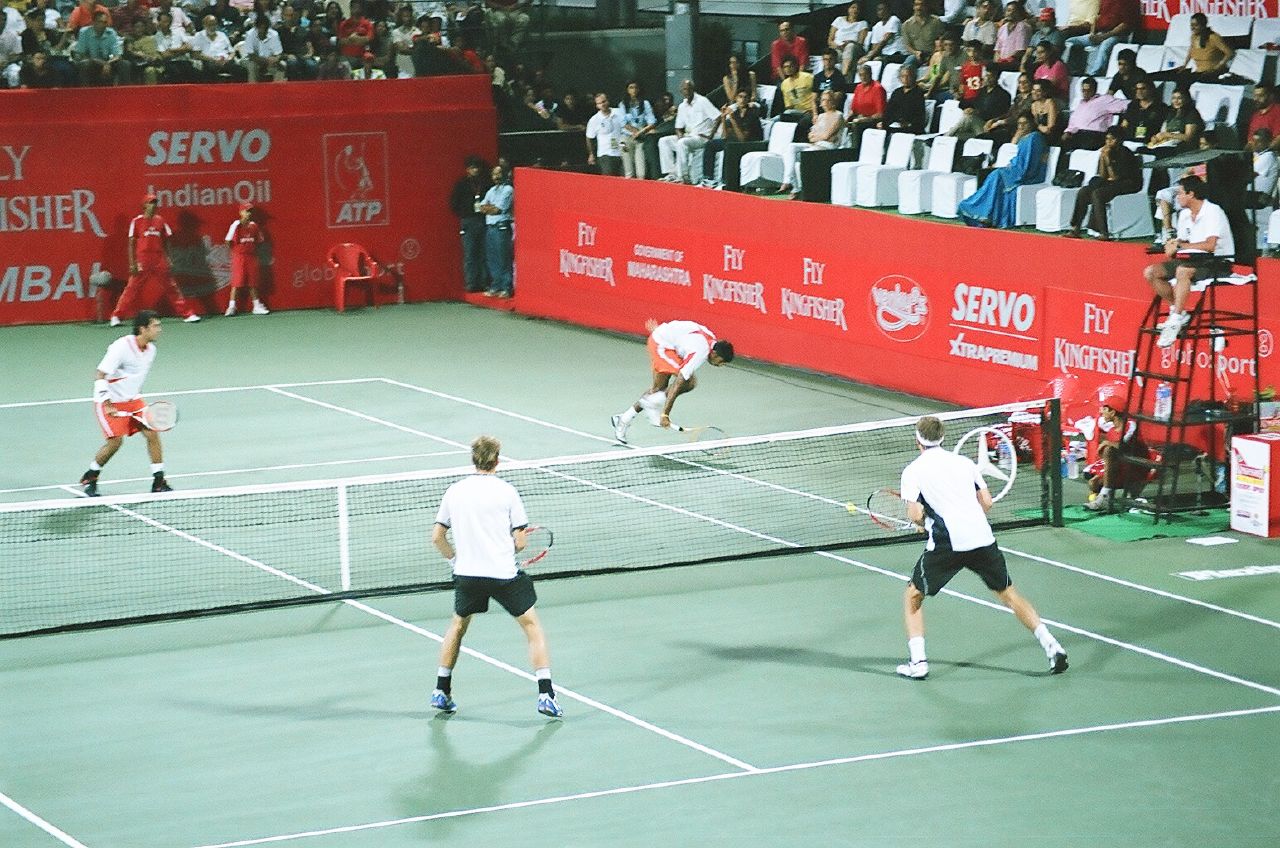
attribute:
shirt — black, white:
[892, 455, 1010, 557]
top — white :
[431, 493, 559, 574]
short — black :
[438, 558, 575, 625]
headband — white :
[894, 381, 1010, 457]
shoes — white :
[871, 607, 1131, 730]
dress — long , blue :
[964, 102, 1024, 260]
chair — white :
[959, 90, 1073, 273]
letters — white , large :
[924, 246, 1047, 401]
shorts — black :
[887, 535, 1089, 644]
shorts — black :
[396, 551, 577, 623]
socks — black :
[510, 660, 565, 701]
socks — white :
[864, 609, 1129, 669]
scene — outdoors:
[37, 25, 1233, 813]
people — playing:
[147, 247, 1080, 717]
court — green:
[649, 633, 851, 842]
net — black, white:
[70, 452, 454, 801]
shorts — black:
[470, 519, 604, 707]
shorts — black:
[396, 526, 544, 660]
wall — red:
[203, 72, 507, 509]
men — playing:
[147, 307, 1001, 798]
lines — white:
[147, 289, 679, 780]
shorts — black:
[432, 556, 534, 614]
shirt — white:
[420, 474, 534, 588]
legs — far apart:
[97, 260, 213, 322]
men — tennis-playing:
[69, 272, 1076, 718]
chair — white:
[830, 130, 883, 197]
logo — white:
[544, 211, 620, 292]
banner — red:
[504, 162, 1274, 450]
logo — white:
[621, 232, 693, 299]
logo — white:
[702, 232, 774, 332]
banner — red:
[502, 167, 1276, 509]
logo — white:
[772, 239, 862, 343]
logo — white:
[858, 267, 937, 348]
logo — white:
[932, 272, 1055, 383]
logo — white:
[1042, 290, 1160, 408]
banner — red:
[502, 151, 1279, 420]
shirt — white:
[439, 467, 539, 585]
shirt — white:
[897, 446, 1006, 550]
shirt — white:
[660, 314, 713, 376]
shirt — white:
[434, 463, 534, 588]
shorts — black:
[458, 570, 548, 609]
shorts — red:
[95, 393, 157, 430]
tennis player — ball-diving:
[609, 304, 739, 429]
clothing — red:
[216, 209, 269, 302]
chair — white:
[863, 121, 918, 207]